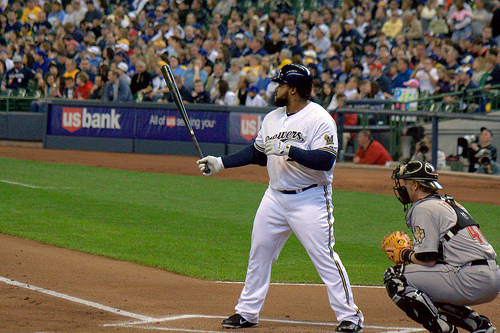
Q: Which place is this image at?
A: It is at the field.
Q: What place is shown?
A: It is a field.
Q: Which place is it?
A: It is a field.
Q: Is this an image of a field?
A: Yes, it is showing a field.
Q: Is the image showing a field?
A: Yes, it is showing a field.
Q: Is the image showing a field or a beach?
A: It is showing a field.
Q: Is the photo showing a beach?
A: No, the picture is showing a field.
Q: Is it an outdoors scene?
A: Yes, it is outdoors.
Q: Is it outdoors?
A: Yes, it is outdoors.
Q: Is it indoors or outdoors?
A: It is outdoors.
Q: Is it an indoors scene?
A: No, it is outdoors.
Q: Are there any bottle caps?
A: No, there are no bottle caps.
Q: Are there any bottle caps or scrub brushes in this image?
A: No, there are no bottle caps or scrub brushes.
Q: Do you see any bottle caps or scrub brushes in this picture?
A: No, there are no bottle caps or scrub brushes.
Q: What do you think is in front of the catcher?
A: The home plate is in front of the catcher.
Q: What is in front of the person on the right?
A: The home plate is in front of the catcher.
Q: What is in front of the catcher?
A: The home plate is in front of the catcher.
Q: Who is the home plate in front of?
A: The home plate is in front of the catcher.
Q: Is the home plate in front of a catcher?
A: Yes, the home plate is in front of a catcher.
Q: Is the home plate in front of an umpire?
A: No, the home plate is in front of a catcher.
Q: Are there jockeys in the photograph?
A: No, there are no jockeys.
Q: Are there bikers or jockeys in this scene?
A: No, there are no jockeys or bikers.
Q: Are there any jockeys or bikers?
A: No, there are no jockeys or bikers.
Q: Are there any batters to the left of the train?
A: Yes, there is a batter to the left of the train.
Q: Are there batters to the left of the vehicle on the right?
A: Yes, there is a batter to the left of the train.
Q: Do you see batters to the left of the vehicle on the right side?
A: Yes, there is a batter to the left of the train.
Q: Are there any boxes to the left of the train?
A: No, there is a batter to the left of the train.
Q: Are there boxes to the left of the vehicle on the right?
A: No, there is a batter to the left of the train.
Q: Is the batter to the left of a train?
A: Yes, the batter is to the left of a train.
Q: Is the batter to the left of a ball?
A: No, the batter is to the left of a train.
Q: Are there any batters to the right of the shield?
A: Yes, there is a batter to the right of the shield.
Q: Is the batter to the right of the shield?
A: Yes, the batter is to the right of the shield.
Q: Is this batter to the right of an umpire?
A: No, the batter is to the right of the shield.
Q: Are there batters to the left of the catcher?
A: Yes, there is a batter to the left of the catcher.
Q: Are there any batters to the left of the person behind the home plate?
A: Yes, there is a batter to the left of the catcher.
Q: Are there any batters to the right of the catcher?
A: No, the batter is to the left of the catcher.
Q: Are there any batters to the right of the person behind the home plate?
A: No, the batter is to the left of the catcher.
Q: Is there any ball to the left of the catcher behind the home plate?
A: No, there is a batter to the left of the catcher.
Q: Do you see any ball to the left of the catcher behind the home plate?
A: No, there is a batter to the left of the catcher.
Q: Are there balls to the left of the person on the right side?
A: No, there is a batter to the left of the catcher.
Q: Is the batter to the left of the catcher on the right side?
A: Yes, the batter is to the left of the catcher.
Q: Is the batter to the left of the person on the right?
A: Yes, the batter is to the left of the catcher.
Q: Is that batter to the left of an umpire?
A: No, the batter is to the left of the catcher.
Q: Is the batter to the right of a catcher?
A: No, the batter is to the left of a catcher.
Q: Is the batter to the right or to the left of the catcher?
A: The batter is to the left of the catcher.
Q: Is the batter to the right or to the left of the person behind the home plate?
A: The batter is to the left of the catcher.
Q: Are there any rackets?
A: No, there are no rackets.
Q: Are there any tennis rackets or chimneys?
A: No, there are no tennis rackets or chimneys.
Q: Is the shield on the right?
A: No, the shield is on the left of the image.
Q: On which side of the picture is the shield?
A: The shield is on the left of the image.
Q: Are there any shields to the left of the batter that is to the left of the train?
A: Yes, there is a shield to the left of the batter.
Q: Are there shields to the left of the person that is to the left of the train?
A: Yes, there is a shield to the left of the batter.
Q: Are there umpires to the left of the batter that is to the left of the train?
A: No, there is a shield to the left of the batter.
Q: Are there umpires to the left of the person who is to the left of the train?
A: No, there is a shield to the left of the batter.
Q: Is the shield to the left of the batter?
A: Yes, the shield is to the left of the batter.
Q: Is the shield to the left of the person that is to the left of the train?
A: Yes, the shield is to the left of the batter.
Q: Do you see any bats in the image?
A: Yes, there is a bat.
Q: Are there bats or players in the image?
A: Yes, there is a bat.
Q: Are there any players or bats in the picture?
A: Yes, there is a bat.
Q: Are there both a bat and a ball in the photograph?
A: No, there is a bat but no balls.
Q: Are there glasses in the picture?
A: No, there are no glasses.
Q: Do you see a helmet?
A: Yes, there is a helmet.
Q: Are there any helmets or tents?
A: Yes, there is a helmet.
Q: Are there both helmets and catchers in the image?
A: Yes, there are both a helmet and a catcher.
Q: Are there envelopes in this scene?
A: No, there are no envelopes.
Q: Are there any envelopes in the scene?
A: No, there are no envelopes.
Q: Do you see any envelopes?
A: No, there are no envelopes.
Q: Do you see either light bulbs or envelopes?
A: No, there are no envelopes or light bulbs.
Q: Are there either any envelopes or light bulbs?
A: No, there are no envelopes or light bulbs.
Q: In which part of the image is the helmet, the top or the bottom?
A: The helmet is in the top of the image.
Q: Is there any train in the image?
A: Yes, there is a train.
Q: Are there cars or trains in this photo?
A: Yes, there is a train.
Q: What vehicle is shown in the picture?
A: The vehicle is a train.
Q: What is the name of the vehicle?
A: The vehicle is a train.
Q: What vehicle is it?
A: The vehicle is a train.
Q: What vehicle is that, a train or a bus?
A: That is a train.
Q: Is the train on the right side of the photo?
A: Yes, the train is on the right of the image.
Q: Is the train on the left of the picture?
A: No, the train is on the right of the image.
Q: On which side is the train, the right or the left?
A: The train is on the right of the image.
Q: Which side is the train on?
A: The train is on the right of the image.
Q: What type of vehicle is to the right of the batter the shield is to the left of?
A: The vehicle is a train.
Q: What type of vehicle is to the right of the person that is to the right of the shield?
A: The vehicle is a train.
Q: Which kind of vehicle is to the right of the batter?
A: The vehicle is a train.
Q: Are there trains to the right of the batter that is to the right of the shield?
A: Yes, there is a train to the right of the batter.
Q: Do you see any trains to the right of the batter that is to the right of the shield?
A: Yes, there is a train to the right of the batter.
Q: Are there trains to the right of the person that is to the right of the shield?
A: Yes, there is a train to the right of the batter.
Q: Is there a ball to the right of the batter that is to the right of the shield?
A: No, there is a train to the right of the batter.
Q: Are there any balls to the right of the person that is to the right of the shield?
A: No, there is a train to the right of the batter.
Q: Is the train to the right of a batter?
A: Yes, the train is to the right of a batter.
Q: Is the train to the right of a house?
A: No, the train is to the right of a batter.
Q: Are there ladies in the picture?
A: No, there are no ladies.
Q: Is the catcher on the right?
A: Yes, the catcher is on the right of the image.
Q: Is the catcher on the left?
A: No, the catcher is on the right of the image.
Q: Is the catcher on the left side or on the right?
A: The catcher is on the right of the image.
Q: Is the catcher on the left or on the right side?
A: The catcher is on the right of the image.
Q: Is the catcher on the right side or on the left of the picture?
A: The catcher is on the right of the image.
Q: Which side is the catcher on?
A: The catcher is on the right of the image.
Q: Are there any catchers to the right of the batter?
A: Yes, there is a catcher to the right of the batter.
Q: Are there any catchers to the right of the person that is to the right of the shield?
A: Yes, there is a catcher to the right of the batter.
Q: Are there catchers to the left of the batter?
A: No, the catcher is to the right of the batter.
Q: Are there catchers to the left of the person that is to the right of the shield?
A: No, the catcher is to the right of the batter.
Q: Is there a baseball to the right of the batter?
A: No, there is a catcher to the right of the batter.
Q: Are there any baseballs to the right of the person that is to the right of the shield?
A: No, there is a catcher to the right of the batter.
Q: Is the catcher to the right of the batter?
A: Yes, the catcher is to the right of the batter.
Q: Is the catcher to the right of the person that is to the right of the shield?
A: Yes, the catcher is to the right of the batter.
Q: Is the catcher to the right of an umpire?
A: No, the catcher is to the right of the batter.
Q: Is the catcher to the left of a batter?
A: No, the catcher is to the right of a batter.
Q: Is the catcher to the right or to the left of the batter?
A: The catcher is to the right of the batter.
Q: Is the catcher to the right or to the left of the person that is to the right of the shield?
A: The catcher is to the right of the batter.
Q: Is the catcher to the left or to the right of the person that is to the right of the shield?
A: The catcher is to the right of the batter.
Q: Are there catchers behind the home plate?
A: Yes, there is a catcher behind the home plate.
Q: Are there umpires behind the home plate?
A: No, there is a catcher behind the home plate.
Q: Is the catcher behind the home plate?
A: Yes, the catcher is behind the home plate.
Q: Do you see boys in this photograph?
A: No, there are no boys.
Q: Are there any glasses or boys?
A: No, there are no boys or glasses.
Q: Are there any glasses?
A: No, there are no glasses.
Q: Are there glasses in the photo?
A: No, there are no glasses.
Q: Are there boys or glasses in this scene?
A: No, there are no glasses or boys.